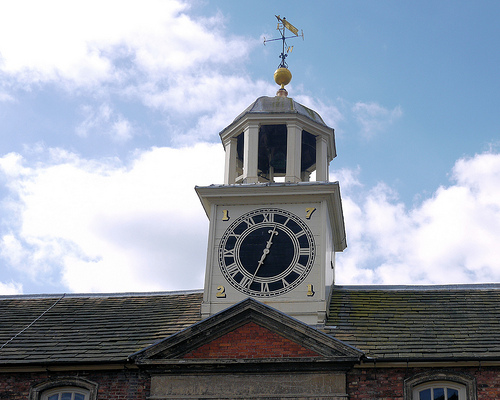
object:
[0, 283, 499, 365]
roof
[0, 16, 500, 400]
bank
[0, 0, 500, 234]
sky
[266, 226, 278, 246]
hands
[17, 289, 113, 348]
section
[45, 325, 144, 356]
section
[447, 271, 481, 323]
section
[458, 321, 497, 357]
section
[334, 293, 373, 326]
section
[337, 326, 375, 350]
section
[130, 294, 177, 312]
section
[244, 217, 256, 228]
number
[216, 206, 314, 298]
clock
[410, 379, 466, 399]
window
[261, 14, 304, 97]
compass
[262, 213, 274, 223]
numeral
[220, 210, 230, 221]
number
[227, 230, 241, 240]
numeral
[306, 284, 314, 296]
number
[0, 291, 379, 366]
gable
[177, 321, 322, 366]
brick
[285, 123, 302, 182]
column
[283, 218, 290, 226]
numeral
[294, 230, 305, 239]
numeral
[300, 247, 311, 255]
roman numeral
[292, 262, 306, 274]
roman numeral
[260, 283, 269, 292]
roman numeral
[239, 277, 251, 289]
roman numeral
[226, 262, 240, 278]
roman numeral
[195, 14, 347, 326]
clock tower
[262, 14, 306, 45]
weather vane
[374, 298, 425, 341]
section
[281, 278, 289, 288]
roman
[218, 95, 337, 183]
open